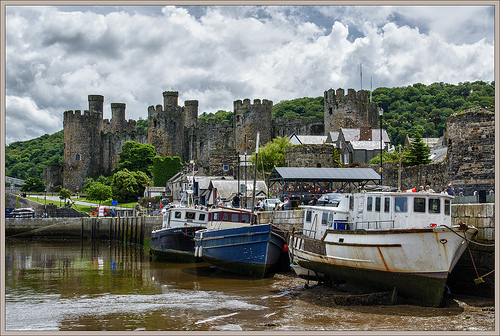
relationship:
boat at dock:
[278, 167, 479, 311] [7, 190, 499, 259]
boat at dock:
[189, 189, 288, 272] [7, 190, 499, 259]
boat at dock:
[141, 193, 217, 264] [7, 190, 499, 259]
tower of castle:
[57, 106, 107, 199] [53, 88, 500, 212]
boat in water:
[278, 167, 479, 311] [3, 233, 499, 336]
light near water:
[376, 105, 386, 188] [3, 233, 499, 336]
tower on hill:
[57, 106, 107, 199] [10, 79, 499, 197]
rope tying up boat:
[440, 221, 499, 261] [278, 167, 479, 311]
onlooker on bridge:
[444, 179, 460, 201] [7, 190, 499, 259]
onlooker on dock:
[444, 182, 456, 202] [7, 190, 499, 259]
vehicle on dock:
[258, 195, 287, 213] [7, 190, 499, 259]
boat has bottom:
[278, 167, 479, 311] [292, 250, 452, 314]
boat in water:
[189, 189, 288, 272] [3, 233, 499, 336]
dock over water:
[7, 190, 499, 259] [3, 233, 499, 336]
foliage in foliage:
[106, 168, 150, 206] [77, 132, 165, 207]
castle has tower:
[53, 88, 500, 212] [57, 106, 107, 199]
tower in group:
[142, 103, 187, 168] [141, 85, 205, 170]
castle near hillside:
[53, 88, 500, 212] [4, 129, 69, 185]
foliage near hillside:
[106, 168, 150, 206] [4, 129, 69, 185]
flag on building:
[264, 182, 334, 201] [199, 177, 269, 209]